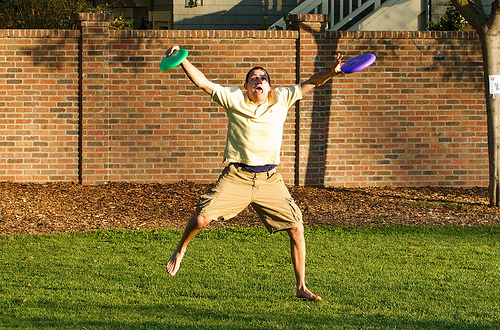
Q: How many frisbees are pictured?
A: Two.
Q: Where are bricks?
A: On a wall.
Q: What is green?
A: Grass.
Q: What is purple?
A: Frisbee on right.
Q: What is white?
A: A railing in the background.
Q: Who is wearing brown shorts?
A: The man.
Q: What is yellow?
A: Man's shirt.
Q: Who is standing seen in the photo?
A: A man.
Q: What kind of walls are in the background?
A: Brick walls.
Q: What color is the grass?
A: Green.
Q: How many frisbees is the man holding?
A: Two.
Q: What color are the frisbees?
A: Green and purple.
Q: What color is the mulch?
A: Brown.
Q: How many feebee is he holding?
A: 2.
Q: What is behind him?
A: Wall.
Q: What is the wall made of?
A: Bricks.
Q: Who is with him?
A: No one.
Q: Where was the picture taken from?
A: In a park.